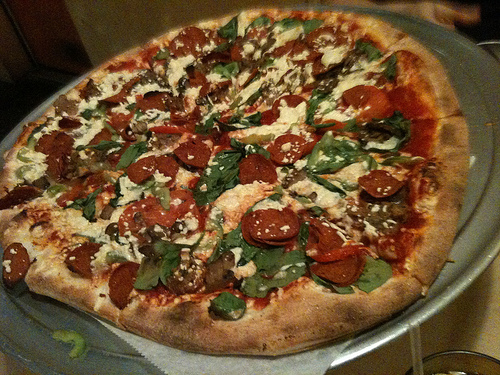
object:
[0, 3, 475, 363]
pizza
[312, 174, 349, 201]
toppings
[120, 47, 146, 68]
crust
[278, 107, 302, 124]
cheese